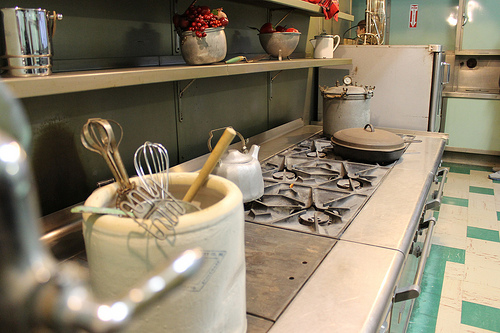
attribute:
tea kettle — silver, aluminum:
[216, 142, 272, 208]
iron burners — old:
[280, 154, 355, 234]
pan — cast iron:
[330, 130, 412, 162]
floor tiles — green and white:
[414, 147, 499, 331]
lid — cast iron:
[331, 125, 406, 152]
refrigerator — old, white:
[316, 42, 450, 134]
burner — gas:
[264, 153, 387, 235]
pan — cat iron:
[325, 114, 411, 159]